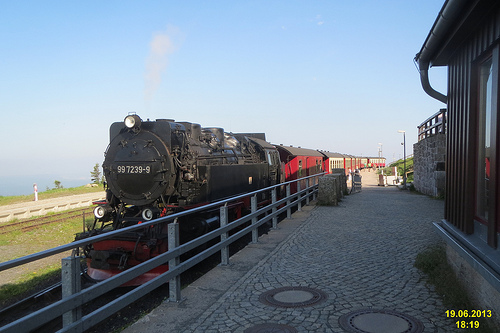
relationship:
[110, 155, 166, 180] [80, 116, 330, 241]
numbers in train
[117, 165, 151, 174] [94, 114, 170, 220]
numbers in train front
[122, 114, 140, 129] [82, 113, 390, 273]
white horn atop train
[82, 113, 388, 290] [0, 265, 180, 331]
car on track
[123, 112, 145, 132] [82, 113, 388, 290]
light on car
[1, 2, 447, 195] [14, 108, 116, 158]
blue sky has clouds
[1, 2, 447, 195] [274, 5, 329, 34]
blue sky has clouds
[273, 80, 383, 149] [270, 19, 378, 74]
clouds in sky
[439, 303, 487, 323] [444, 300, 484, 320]
timestamp stamp corner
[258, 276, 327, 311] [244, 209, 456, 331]
designs in concrete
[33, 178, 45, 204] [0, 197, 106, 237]
pole on grass tracks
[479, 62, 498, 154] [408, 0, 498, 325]
window on building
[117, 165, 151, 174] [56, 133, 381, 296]
numbers on train